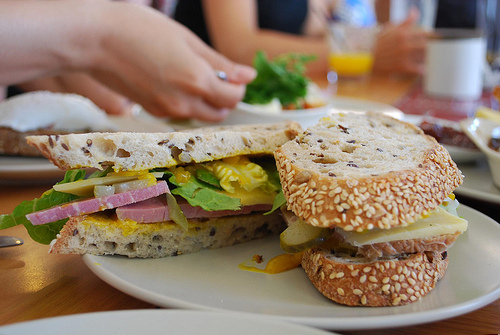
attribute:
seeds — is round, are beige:
[292, 184, 420, 236]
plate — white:
[69, 147, 497, 331]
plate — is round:
[80, 171, 498, 330]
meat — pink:
[102, 191, 204, 246]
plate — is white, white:
[80, 193, 496, 330]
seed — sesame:
[331, 194, 342, 204]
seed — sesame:
[334, 204, 345, 212]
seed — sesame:
[339, 202, 351, 211]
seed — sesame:
[352, 185, 359, 195]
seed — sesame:
[340, 212, 347, 224]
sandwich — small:
[276, 112, 463, 302]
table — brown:
[3, 168, 499, 328]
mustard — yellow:
[257, 251, 307, 276]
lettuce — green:
[183, 184, 245, 214]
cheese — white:
[203, 90, 451, 266]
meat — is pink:
[22, 178, 262, 225]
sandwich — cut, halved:
[114, 110, 361, 247]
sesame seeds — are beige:
[275, 158, 458, 308]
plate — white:
[81, 200, 481, 323]